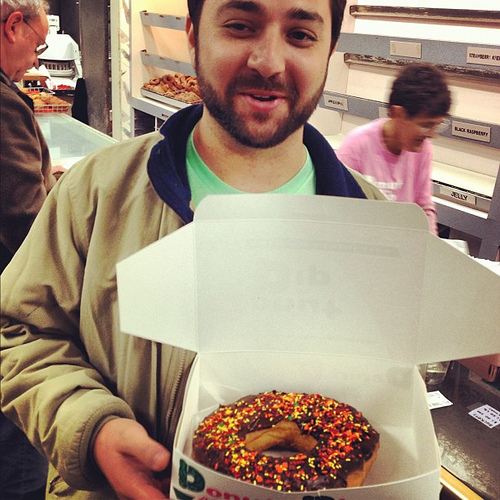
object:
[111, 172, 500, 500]
box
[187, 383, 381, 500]
donut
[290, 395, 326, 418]
sprinkles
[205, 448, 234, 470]
chocolate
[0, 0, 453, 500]
man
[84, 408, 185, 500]
hand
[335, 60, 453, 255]
woman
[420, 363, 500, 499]
counter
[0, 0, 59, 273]
man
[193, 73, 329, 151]
bear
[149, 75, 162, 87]
donut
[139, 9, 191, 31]
shelf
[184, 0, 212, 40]
hair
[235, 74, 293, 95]
moustache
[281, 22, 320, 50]
eyes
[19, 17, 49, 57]
glasses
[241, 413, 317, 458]
hole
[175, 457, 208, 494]
letters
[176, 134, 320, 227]
shirt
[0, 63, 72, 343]
jacket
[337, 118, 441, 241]
shirt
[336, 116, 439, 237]
pink